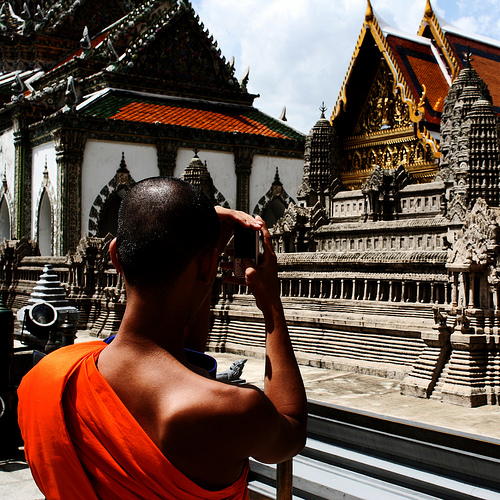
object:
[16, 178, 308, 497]
man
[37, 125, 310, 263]
building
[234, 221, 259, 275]
camera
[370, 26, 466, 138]
trim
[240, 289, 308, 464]
arm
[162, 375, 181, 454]
bone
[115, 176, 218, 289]
hair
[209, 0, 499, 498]
temple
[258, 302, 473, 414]
step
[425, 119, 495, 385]
statue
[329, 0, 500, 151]
roof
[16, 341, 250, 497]
clothing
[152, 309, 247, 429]
skin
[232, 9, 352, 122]
sky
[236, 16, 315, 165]
cloud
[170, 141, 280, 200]
wall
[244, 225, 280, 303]
hand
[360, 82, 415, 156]
design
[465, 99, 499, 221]
pillar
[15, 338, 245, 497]
back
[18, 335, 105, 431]
shoulder